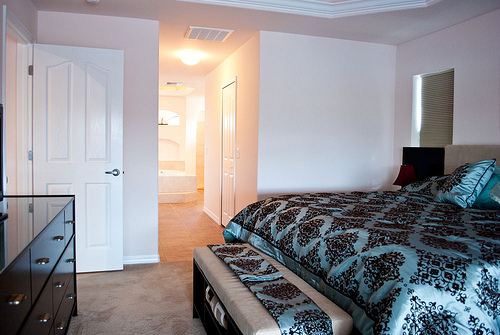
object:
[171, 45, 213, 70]
light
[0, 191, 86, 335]
dresser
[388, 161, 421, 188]
lamp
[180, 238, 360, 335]
bench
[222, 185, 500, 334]
bed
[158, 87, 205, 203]
bathroom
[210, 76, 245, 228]
closet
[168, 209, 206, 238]
floor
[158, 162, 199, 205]
bathtub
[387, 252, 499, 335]
bedspread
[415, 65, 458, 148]
window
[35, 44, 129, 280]
door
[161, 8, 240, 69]
ceiling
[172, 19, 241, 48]
vent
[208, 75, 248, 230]
door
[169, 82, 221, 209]
hallway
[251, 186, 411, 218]
blanket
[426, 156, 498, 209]
pillow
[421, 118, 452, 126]
blinds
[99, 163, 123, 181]
handle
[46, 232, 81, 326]
drawer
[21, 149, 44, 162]
hinge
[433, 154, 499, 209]
comforter